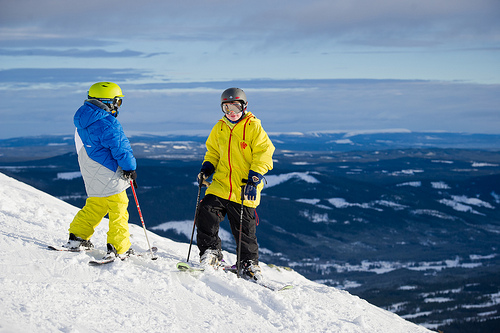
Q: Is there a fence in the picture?
A: No, there are no fences.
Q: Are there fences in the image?
A: No, there are no fences.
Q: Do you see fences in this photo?
A: No, there are no fences.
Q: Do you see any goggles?
A: Yes, there are goggles.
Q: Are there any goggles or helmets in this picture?
A: Yes, there are goggles.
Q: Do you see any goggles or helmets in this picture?
A: Yes, there are goggles.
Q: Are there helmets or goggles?
A: Yes, there are goggles.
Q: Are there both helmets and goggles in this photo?
A: Yes, there are both goggles and a helmet.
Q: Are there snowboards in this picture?
A: No, there are no snowboards.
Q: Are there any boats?
A: No, there are no boats.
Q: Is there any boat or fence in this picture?
A: No, there are no boats or fences.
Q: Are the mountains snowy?
A: Yes, the mountains are snowy.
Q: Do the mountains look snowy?
A: Yes, the mountains are snowy.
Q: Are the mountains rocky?
A: No, the mountains are snowy.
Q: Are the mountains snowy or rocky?
A: The mountains are snowy.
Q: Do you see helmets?
A: Yes, there is a helmet.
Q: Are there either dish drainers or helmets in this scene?
A: Yes, there is a helmet.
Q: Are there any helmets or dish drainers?
A: Yes, there is a helmet.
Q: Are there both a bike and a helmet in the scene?
A: No, there is a helmet but no bikes.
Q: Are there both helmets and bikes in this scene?
A: No, there is a helmet but no bikes.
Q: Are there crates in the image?
A: No, there are no crates.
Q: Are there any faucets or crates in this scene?
A: No, there are no crates or faucets.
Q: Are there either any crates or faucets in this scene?
A: No, there are no crates or faucets.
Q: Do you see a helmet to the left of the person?
A: Yes, there is a helmet to the left of the person.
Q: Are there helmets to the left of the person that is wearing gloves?
A: Yes, there is a helmet to the left of the person.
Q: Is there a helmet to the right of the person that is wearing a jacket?
A: No, the helmet is to the left of the person.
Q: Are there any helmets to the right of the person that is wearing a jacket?
A: No, the helmet is to the left of the person.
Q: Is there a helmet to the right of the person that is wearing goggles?
A: No, the helmet is to the left of the person.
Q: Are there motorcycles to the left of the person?
A: No, there is a helmet to the left of the person.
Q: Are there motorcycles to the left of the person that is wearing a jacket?
A: No, there is a helmet to the left of the person.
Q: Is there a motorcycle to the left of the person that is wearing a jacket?
A: No, there is a helmet to the left of the person.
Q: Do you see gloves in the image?
A: Yes, there are gloves.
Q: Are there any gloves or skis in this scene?
A: Yes, there are gloves.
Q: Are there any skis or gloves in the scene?
A: Yes, there are gloves.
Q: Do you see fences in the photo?
A: No, there are no fences.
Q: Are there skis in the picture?
A: Yes, there are skis.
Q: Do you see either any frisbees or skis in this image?
A: Yes, there are skis.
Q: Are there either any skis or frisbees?
A: Yes, there are skis.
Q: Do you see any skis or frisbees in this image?
A: Yes, there are skis.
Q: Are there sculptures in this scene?
A: No, there are no sculptures.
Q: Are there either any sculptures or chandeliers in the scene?
A: No, there are no sculptures or chandeliers.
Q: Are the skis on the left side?
A: Yes, the skis are on the left of the image.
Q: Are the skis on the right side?
A: No, the skis are on the left of the image.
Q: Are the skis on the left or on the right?
A: The skis are on the left of the image.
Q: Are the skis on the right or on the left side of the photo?
A: The skis are on the left of the image.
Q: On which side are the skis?
A: The skis are on the left of the image.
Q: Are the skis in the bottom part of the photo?
A: Yes, the skis are in the bottom of the image.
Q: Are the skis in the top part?
A: No, the skis are in the bottom of the image.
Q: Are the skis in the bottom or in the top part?
A: The skis are in the bottom of the image.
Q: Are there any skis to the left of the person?
A: Yes, there are skis to the left of the person.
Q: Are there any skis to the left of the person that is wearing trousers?
A: Yes, there are skis to the left of the person.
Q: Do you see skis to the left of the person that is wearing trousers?
A: Yes, there are skis to the left of the person.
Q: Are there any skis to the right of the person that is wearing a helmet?
A: No, the skis are to the left of the person.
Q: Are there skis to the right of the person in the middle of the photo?
A: No, the skis are to the left of the person.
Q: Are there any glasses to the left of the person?
A: No, there are skis to the left of the person.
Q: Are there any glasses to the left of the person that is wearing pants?
A: No, there are skis to the left of the person.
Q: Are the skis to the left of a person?
A: Yes, the skis are to the left of a person.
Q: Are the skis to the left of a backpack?
A: No, the skis are to the left of a person.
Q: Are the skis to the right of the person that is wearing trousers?
A: No, the skis are to the left of the person.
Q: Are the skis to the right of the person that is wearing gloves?
A: No, the skis are to the left of the person.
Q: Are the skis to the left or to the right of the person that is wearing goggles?
A: The skis are to the left of the person.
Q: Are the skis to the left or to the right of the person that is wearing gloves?
A: The skis are to the left of the person.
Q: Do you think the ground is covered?
A: Yes, the ground is covered.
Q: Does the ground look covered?
A: Yes, the ground is covered.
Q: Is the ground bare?
A: No, the ground is covered.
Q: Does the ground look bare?
A: No, the ground is covered.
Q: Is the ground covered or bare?
A: The ground is covered.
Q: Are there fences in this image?
A: No, there are no fences.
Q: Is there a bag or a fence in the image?
A: No, there are no fences or bags.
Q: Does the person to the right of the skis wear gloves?
A: Yes, the person wears gloves.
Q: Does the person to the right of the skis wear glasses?
A: No, the person wears gloves.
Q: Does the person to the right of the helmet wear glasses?
A: No, the person wears gloves.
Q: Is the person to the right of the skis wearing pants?
A: Yes, the person is wearing pants.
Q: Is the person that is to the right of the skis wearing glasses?
A: No, the person is wearing pants.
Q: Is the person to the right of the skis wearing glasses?
A: No, the person is wearing pants.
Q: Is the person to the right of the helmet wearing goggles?
A: Yes, the person is wearing goggles.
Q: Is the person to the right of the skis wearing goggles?
A: Yes, the person is wearing goggles.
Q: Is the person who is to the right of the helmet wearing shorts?
A: No, the person is wearing goggles.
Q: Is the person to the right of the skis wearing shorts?
A: No, the person is wearing goggles.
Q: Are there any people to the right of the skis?
A: Yes, there is a person to the right of the skis.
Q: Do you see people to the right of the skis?
A: Yes, there is a person to the right of the skis.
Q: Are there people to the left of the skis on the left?
A: No, the person is to the right of the skis.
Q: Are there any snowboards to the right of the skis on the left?
A: No, there is a person to the right of the skis.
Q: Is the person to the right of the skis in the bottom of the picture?
A: Yes, the person is to the right of the skis.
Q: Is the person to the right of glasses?
A: No, the person is to the right of the skis.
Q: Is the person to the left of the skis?
A: No, the person is to the right of the skis.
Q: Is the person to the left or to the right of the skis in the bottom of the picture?
A: The person is to the right of the skis.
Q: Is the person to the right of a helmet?
A: Yes, the person is to the right of a helmet.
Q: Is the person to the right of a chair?
A: No, the person is to the right of a helmet.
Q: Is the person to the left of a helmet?
A: No, the person is to the right of a helmet.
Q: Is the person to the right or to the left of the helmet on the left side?
A: The person is to the right of the helmet.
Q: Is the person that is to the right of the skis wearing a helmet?
A: Yes, the person is wearing a helmet.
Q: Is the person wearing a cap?
A: No, the person is wearing a helmet.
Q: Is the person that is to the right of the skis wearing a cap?
A: No, the person is wearing a helmet.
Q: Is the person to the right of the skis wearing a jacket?
A: Yes, the person is wearing a jacket.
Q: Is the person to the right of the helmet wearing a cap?
A: No, the person is wearing a jacket.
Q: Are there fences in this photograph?
A: No, there are no fences.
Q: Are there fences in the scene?
A: No, there are no fences.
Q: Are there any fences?
A: No, there are no fences.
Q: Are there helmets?
A: Yes, there is a helmet.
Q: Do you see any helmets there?
A: Yes, there is a helmet.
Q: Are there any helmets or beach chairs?
A: Yes, there is a helmet.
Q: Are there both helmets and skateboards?
A: No, there is a helmet but no skateboards.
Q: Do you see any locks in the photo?
A: No, there are no locks.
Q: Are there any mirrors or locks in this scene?
A: No, there are no locks or mirrors.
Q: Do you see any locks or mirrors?
A: No, there are no locks or mirrors.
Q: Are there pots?
A: No, there are no pots.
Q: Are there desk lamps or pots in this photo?
A: No, there are no pots or desk lamps.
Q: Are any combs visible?
A: No, there are no combs.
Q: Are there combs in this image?
A: No, there are no combs.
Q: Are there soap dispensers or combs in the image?
A: No, there are no combs or soap dispensers.